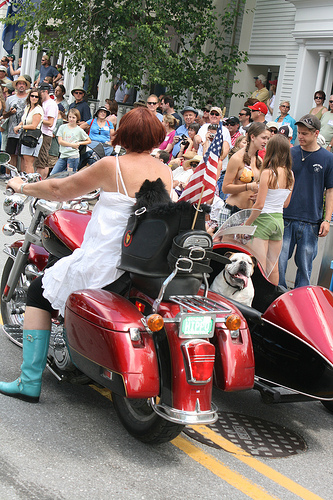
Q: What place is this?
A: It is a street.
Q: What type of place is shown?
A: It is a street.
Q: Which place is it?
A: It is a street.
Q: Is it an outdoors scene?
A: Yes, it is outdoors.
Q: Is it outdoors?
A: Yes, it is outdoors.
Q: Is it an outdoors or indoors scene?
A: It is outdoors.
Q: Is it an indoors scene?
A: No, it is outdoors.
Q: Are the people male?
A: No, they are both male and female.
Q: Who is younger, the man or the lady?
A: The man is younger than the lady.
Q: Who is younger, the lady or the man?
A: The man is younger than the lady.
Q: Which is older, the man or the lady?
A: The lady is older than the man.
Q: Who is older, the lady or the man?
A: The lady is older than the man.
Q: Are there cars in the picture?
A: No, there are no cars.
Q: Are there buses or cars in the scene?
A: No, there are no cars or buses.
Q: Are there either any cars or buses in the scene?
A: No, there are no cars or buses.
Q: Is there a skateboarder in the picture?
A: No, there are no skateboarders.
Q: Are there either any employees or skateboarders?
A: No, there are no skateboarders or employees.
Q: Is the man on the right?
A: Yes, the man is on the right of the image.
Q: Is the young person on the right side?
A: Yes, the man is on the right of the image.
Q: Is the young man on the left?
A: No, the man is on the right of the image.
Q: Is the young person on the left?
A: No, the man is on the right of the image.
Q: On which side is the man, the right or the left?
A: The man is on the right of the image.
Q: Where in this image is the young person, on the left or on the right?
A: The man is on the right of the image.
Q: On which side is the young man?
A: The man is on the right of the image.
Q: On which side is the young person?
A: The man is on the right of the image.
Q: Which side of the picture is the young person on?
A: The man is on the right of the image.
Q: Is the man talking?
A: Yes, the man is talking.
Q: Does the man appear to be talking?
A: Yes, the man is talking.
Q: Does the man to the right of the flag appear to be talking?
A: Yes, the man is talking.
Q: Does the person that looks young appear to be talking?
A: Yes, the man is talking.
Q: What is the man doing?
A: The man is talking.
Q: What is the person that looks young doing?
A: The man is talking.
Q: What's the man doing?
A: The man is talking.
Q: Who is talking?
A: The man is talking.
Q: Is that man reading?
A: No, the man is talking.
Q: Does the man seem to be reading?
A: No, the man is talking.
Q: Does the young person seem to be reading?
A: No, the man is talking.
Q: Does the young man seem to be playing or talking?
A: The man is talking.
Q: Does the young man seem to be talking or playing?
A: The man is talking.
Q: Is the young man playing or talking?
A: The man is talking.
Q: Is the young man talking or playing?
A: The man is talking.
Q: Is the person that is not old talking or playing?
A: The man is talking.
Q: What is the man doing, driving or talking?
A: The man is talking.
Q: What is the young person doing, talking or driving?
A: The man is talking.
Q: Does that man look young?
A: Yes, the man is young.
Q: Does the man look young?
A: Yes, the man is young.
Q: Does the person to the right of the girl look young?
A: Yes, the man is young.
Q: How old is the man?
A: The man is young.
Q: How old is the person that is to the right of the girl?
A: The man is young.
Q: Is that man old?
A: No, the man is young.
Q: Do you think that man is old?
A: No, the man is young.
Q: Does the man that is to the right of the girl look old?
A: No, the man is young.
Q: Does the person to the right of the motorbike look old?
A: No, the man is young.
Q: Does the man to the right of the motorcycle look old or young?
A: The man is young.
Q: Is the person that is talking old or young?
A: The man is young.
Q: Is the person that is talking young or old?
A: The man is young.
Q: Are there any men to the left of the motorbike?
A: No, the man is to the right of the motorbike.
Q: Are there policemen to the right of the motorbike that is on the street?
A: No, there is a man to the right of the motorcycle.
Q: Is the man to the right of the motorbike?
A: Yes, the man is to the right of the motorbike.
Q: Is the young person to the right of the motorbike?
A: Yes, the man is to the right of the motorbike.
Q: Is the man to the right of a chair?
A: No, the man is to the right of the motorbike.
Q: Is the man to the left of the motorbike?
A: No, the man is to the right of the motorbike.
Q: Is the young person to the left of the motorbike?
A: No, the man is to the right of the motorbike.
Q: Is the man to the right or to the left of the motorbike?
A: The man is to the right of the motorbike.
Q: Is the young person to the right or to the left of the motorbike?
A: The man is to the right of the motorbike.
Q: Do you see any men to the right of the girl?
A: Yes, there is a man to the right of the girl.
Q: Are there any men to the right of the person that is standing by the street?
A: Yes, there is a man to the right of the girl.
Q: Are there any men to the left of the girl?
A: No, the man is to the right of the girl.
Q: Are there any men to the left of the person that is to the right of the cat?
A: No, the man is to the right of the girl.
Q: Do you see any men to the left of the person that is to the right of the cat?
A: No, the man is to the right of the girl.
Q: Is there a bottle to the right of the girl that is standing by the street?
A: No, there is a man to the right of the girl.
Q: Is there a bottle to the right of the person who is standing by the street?
A: No, there is a man to the right of the girl.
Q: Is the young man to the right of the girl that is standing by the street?
A: Yes, the man is to the right of the girl.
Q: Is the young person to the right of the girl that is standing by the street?
A: Yes, the man is to the right of the girl.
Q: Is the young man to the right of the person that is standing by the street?
A: Yes, the man is to the right of the girl.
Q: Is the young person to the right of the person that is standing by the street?
A: Yes, the man is to the right of the girl.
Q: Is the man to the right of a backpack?
A: No, the man is to the right of the girl.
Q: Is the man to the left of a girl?
A: No, the man is to the right of a girl.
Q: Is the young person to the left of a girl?
A: No, the man is to the right of a girl.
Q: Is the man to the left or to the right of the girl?
A: The man is to the right of the girl.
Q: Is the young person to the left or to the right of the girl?
A: The man is to the right of the girl.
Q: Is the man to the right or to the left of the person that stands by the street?
A: The man is to the right of the girl.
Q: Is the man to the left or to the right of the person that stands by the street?
A: The man is to the right of the girl.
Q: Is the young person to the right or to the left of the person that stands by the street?
A: The man is to the right of the girl.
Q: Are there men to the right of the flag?
A: Yes, there is a man to the right of the flag.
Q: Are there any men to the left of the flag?
A: No, the man is to the right of the flag.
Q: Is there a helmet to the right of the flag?
A: No, there is a man to the right of the flag.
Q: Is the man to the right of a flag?
A: Yes, the man is to the right of a flag.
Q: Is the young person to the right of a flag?
A: Yes, the man is to the right of a flag.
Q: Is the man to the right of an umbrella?
A: No, the man is to the right of a flag.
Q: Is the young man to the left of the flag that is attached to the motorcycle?
A: No, the man is to the right of the flag.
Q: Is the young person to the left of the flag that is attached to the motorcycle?
A: No, the man is to the right of the flag.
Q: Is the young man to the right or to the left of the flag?
A: The man is to the right of the flag.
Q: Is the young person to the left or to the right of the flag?
A: The man is to the right of the flag.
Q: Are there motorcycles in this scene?
A: Yes, there is a motorcycle.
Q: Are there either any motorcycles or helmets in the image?
A: Yes, there is a motorcycle.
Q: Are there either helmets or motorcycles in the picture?
A: Yes, there is a motorcycle.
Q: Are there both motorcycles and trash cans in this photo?
A: No, there is a motorcycle but no trash cans.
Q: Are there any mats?
A: No, there are no mats.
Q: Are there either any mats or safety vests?
A: No, there are no mats or safety vests.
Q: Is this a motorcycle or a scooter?
A: This is a motorcycle.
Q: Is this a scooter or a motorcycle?
A: This is a motorcycle.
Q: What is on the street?
A: The motorbike is on the street.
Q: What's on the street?
A: The motorbike is on the street.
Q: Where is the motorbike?
A: The motorbike is on the street.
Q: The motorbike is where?
A: The motorbike is on the street.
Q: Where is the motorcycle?
A: The motorbike is on the street.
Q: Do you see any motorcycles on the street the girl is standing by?
A: Yes, there is a motorcycle on the street.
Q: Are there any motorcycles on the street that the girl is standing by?
A: Yes, there is a motorcycle on the street.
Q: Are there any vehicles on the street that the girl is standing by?
A: No, there is a motorcycle on the street.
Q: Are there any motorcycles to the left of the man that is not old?
A: Yes, there is a motorcycle to the left of the man.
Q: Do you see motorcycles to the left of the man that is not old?
A: Yes, there is a motorcycle to the left of the man.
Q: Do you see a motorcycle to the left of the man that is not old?
A: Yes, there is a motorcycle to the left of the man.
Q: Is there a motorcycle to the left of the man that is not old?
A: Yes, there is a motorcycle to the left of the man.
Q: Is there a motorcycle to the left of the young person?
A: Yes, there is a motorcycle to the left of the man.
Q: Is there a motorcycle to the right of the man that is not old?
A: No, the motorcycle is to the left of the man.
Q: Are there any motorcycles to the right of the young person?
A: No, the motorcycle is to the left of the man.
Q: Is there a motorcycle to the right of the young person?
A: No, the motorcycle is to the left of the man.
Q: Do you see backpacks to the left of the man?
A: No, there is a motorcycle to the left of the man.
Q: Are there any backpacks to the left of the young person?
A: No, there is a motorcycle to the left of the man.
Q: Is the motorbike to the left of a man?
A: Yes, the motorbike is to the left of a man.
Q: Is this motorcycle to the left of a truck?
A: No, the motorcycle is to the left of a man.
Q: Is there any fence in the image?
A: No, there are no fences.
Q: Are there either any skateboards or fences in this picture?
A: No, there are no fences or skateboards.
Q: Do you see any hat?
A: Yes, there is a hat.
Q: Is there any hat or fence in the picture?
A: Yes, there is a hat.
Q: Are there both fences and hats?
A: No, there is a hat but no fences.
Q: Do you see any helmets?
A: No, there are no helmets.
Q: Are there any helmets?
A: No, there are no helmets.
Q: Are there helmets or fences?
A: No, there are no helmets or fences.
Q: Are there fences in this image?
A: No, there are no fences.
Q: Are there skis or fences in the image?
A: No, there are no fences or skis.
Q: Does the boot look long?
A: Yes, the boot is long.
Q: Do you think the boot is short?
A: No, the boot is long.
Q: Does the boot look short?
A: No, the boot is long.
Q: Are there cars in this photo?
A: No, there are no cars.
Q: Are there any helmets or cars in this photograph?
A: No, there are no cars or helmets.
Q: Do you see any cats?
A: Yes, there is a cat.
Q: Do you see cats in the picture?
A: Yes, there is a cat.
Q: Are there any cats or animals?
A: Yes, there is a cat.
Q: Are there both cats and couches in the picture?
A: No, there is a cat but no couches.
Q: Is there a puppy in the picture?
A: No, there are no puppies.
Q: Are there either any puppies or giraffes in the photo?
A: No, there are no puppies or giraffes.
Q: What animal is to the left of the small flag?
A: The animal is a cat.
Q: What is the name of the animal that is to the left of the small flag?
A: The animal is a cat.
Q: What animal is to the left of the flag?
A: The animal is a cat.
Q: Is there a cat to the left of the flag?
A: Yes, there is a cat to the left of the flag.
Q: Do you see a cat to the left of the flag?
A: Yes, there is a cat to the left of the flag.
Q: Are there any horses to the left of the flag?
A: No, there is a cat to the left of the flag.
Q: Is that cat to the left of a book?
A: No, the cat is to the left of a flag.